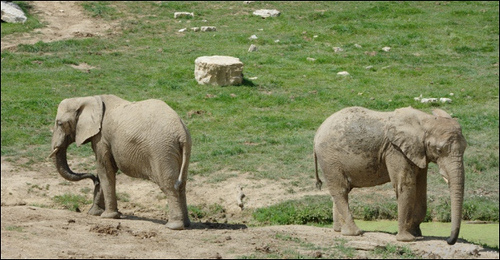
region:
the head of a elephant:
[31, 69, 142, 181]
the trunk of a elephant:
[35, 138, 137, 195]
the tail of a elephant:
[158, 120, 230, 201]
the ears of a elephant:
[66, 88, 133, 156]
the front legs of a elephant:
[84, 128, 126, 218]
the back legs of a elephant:
[144, 108, 245, 249]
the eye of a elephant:
[48, 105, 83, 137]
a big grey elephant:
[287, 68, 492, 223]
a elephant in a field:
[46, 54, 272, 231]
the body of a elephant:
[74, 71, 306, 207]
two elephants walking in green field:
[35, 67, 470, 252]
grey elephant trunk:
[434, 161, 476, 247]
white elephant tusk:
[433, 168, 457, 188]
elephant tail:
[305, 143, 326, 193]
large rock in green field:
[182, 45, 254, 92]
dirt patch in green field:
[6, 156, 241, 258]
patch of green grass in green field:
[219, 98, 291, 148]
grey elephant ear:
[382, 104, 434, 170]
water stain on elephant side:
[343, 108, 403, 175]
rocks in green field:
[247, 25, 394, 81]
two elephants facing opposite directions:
[53, 93, 463, 243]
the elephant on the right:
[311, 106, 466, 242]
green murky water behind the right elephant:
[317, 221, 495, 246]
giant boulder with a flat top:
[193, 54, 243, 87]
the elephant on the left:
[52, 95, 191, 225]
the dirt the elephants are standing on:
[7, 163, 496, 258]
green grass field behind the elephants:
[3, 0, 490, 177]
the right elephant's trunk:
[445, 151, 465, 244]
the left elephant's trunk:
[50, 132, 97, 185]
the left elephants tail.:
[175, 135, 187, 190]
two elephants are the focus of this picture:
[35, 82, 497, 251]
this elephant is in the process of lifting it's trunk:
[38, 94, 204, 236]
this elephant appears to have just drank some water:
[289, 99, 481, 254]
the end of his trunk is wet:
[437, 215, 462, 244]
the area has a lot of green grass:
[1, 15, 483, 255]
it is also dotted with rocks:
[157, 5, 397, 92]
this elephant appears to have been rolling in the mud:
[333, 95, 410, 170]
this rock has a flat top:
[193, 49, 249, 85]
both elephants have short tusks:
[39, 91, 485, 192]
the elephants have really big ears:
[56, 77, 438, 180]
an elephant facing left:
[43, 89, 196, 230]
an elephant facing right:
[309, 92, 469, 244]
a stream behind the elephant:
[295, 205, 498, 250]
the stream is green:
[345, 214, 497, 244]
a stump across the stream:
[180, 52, 253, 86]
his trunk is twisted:
[45, 140, 104, 192]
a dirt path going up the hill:
[0, 1, 115, 63]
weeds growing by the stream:
[257, 199, 337, 225]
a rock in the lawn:
[332, 64, 352, 86]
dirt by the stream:
[8, 202, 483, 259]